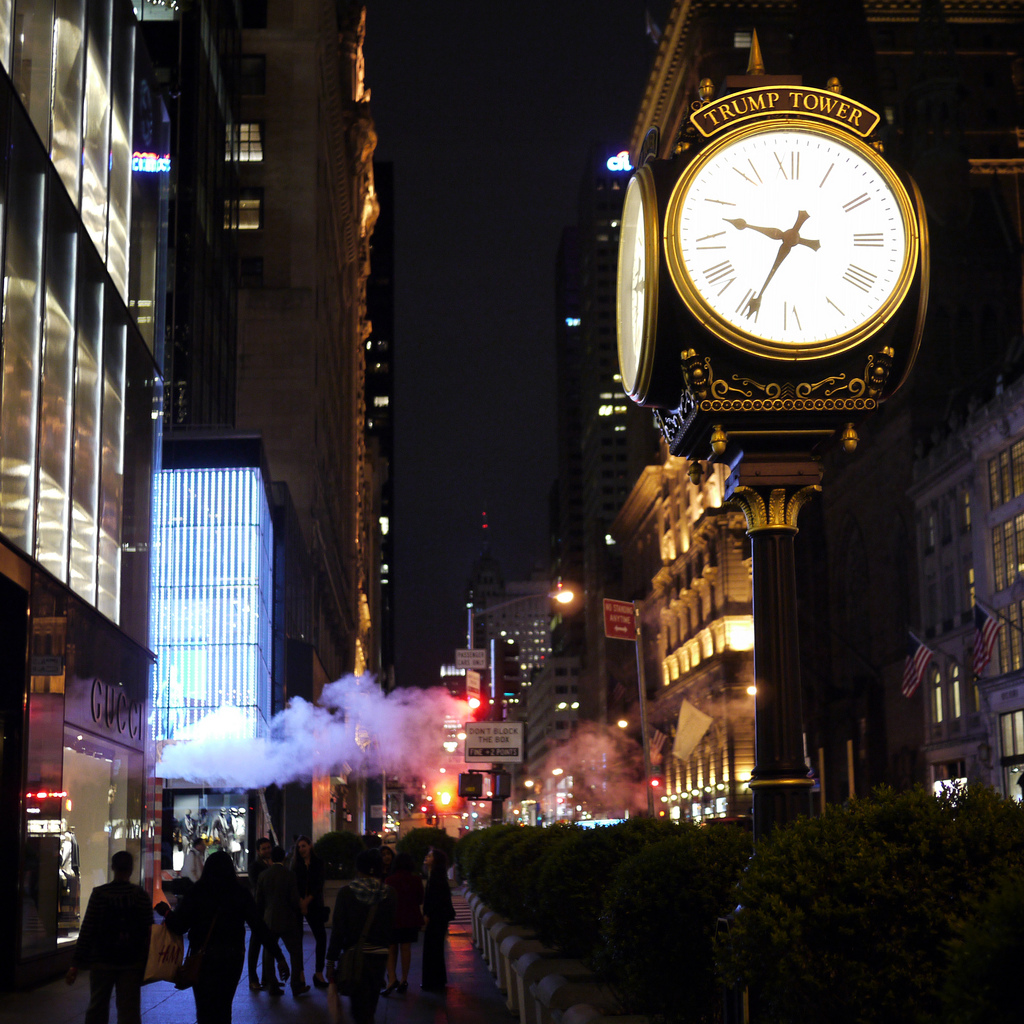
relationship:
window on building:
[689, 741, 727, 798] [15, 145, 214, 969]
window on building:
[97, 318, 145, 547] [0, 7, 373, 950]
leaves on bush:
[822, 832, 922, 896] [862, 784, 984, 1015]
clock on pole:
[605, 149, 672, 409] [741, 471, 814, 827]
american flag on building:
[944, 605, 1009, 675] [886, 367, 1020, 862]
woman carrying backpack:
[312, 842, 437, 1020] [331, 882, 404, 991]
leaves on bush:
[572, 912, 605, 938] [470, 809, 1009, 1019]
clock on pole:
[661, 103, 922, 386] [693, 437, 815, 881]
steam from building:
[171, 651, 498, 797] [557, 467, 778, 841]